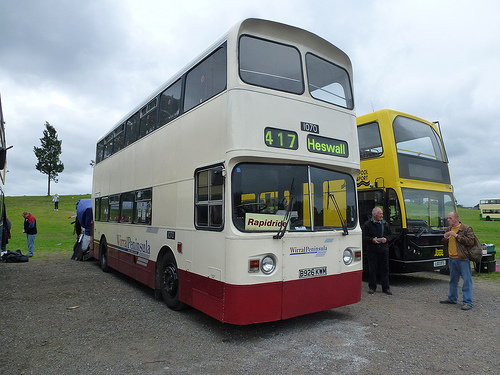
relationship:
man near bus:
[364, 203, 396, 299] [91, 16, 366, 326]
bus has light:
[91, 16, 366, 326] [260, 253, 277, 274]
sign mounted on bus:
[243, 213, 294, 233] [91, 16, 366, 326]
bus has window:
[91, 16, 366, 326] [236, 29, 305, 96]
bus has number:
[91, 16, 366, 326] [263, 126, 298, 147]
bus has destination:
[91, 16, 366, 326] [307, 134, 348, 158]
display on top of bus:
[259, 123, 355, 163] [91, 16, 366, 326]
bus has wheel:
[91, 16, 366, 326] [157, 249, 187, 313]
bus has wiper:
[91, 16, 366, 326] [273, 177, 299, 242]